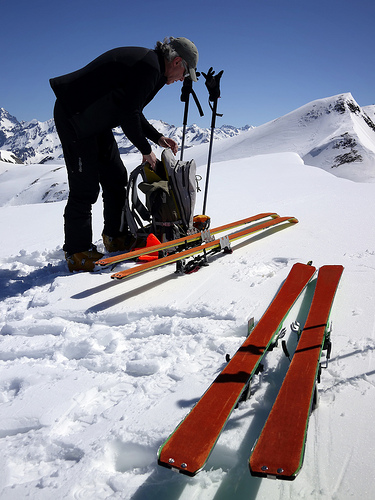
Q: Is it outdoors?
A: Yes, it is outdoors.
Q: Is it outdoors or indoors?
A: It is outdoors.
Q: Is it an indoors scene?
A: No, it is outdoors.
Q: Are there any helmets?
A: No, there are no helmets.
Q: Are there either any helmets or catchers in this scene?
A: No, there are no helmets or catchers.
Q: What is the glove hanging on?
A: The glove is hanging on the pole.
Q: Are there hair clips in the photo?
A: No, there are no hair clips.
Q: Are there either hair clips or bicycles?
A: No, there are no hair clips or bicycles.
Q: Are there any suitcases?
A: No, there are no suitcases.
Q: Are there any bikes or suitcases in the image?
A: No, there are no suitcases or bikes.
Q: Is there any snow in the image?
A: Yes, there is snow.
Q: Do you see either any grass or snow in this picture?
A: Yes, there is snow.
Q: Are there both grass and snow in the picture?
A: No, there is snow but no grass.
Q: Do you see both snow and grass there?
A: No, there is snow but no grass.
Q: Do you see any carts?
A: No, there are no carts.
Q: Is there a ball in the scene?
A: No, there are no balls.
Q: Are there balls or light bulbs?
A: No, there are no balls or light bulbs.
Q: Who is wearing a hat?
A: The man is wearing a hat.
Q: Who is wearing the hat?
A: The man is wearing a hat.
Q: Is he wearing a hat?
A: Yes, the man is wearing a hat.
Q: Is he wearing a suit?
A: No, the man is wearing a hat.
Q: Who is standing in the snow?
A: The man is standing in the snow.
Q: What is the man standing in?
A: The man is standing in the snow.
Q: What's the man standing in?
A: The man is standing in the snow.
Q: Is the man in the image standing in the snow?
A: Yes, the man is standing in the snow.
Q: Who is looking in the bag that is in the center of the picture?
A: The man is looking in the backpack.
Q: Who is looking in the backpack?
A: The man is looking in the backpack.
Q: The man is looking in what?
A: The man is looking in the backpack.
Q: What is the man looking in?
A: The man is looking in the backpack.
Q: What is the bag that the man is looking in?
A: The bag is a backpack.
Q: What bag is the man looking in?
A: The man is looking in the backpack.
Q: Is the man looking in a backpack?
A: Yes, the man is looking in a backpack.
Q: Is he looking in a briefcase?
A: No, the man is looking in a backpack.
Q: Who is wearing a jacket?
A: The man is wearing a jacket.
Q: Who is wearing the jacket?
A: The man is wearing a jacket.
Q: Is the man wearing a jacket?
A: Yes, the man is wearing a jacket.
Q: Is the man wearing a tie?
A: No, the man is wearing a jacket.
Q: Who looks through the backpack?
A: The man looks through the backpack.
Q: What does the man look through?
A: The man looks through the backpack.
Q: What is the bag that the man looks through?
A: The bag is a backpack.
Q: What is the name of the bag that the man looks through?
A: The bag is a backpack.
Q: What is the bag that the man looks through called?
A: The bag is a backpack.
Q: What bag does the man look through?
A: The man looks through the backpack.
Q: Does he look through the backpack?
A: Yes, the man looks through the backpack.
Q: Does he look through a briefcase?
A: No, the man looks through the backpack.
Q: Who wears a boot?
A: The man wears a boot.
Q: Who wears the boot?
A: The man wears a boot.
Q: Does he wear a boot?
A: Yes, the man wears a boot.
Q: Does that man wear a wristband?
A: No, the man wears a boot.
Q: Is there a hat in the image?
A: Yes, there is a hat.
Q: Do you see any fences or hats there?
A: Yes, there is a hat.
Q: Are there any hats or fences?
A: Yes, there is a hat.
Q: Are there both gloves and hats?
A: Yes, there are both a hat and gloves.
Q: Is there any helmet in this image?
A: No, there are no helmets.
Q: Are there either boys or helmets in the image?
A: No, there are no helmets or boys.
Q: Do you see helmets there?
A: No, there are no helmets.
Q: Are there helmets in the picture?
A: No, there are no helmets.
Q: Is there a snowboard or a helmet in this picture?
A: No, there are no helmets or snowboards.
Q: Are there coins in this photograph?
A: No, there are no coins.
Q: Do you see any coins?
A: No, there are no coins.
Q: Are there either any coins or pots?
A: No, there are no coins or pots.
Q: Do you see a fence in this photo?
A: No, there are no fences.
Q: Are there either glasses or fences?
A: No, there are no fences or glasses.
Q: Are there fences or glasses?
A: No, there are no fences or glasses.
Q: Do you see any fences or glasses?
A: No, there are no fences or glasses.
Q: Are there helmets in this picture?
A: No, there are no helmets.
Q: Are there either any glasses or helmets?
A: No, there are no helmets or glasses.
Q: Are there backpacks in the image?
A: Yes, there is a backpack.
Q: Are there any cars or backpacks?
A: Yes, there is a backpack.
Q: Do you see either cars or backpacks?
A: Yes, there is a backpack.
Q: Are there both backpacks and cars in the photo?
A: No, there is a backpack but no cars.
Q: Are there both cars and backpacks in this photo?
A: No, there is a backpack but no cars.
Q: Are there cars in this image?
A: No, there are no cars.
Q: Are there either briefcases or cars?
A: No, there are no cars or briefcases.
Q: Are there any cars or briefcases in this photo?
A: No, there are no cars or briefcases.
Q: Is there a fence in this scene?
A: No, there are no fences.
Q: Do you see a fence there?
A: No, there are no fences.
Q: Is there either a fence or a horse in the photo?
A: No, there are no fences or horses.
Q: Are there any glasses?
A: No, there are no glasses.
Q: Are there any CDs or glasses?
A: No, there are no glasses or cds.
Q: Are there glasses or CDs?
A: No, there are no glasses or cds.